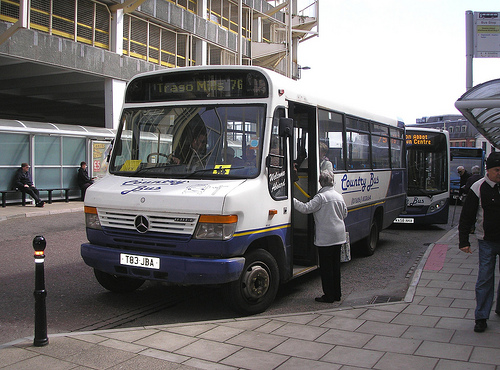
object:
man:
[12, 162, 44, 207]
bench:
[47, 188, 70, 204]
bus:
[79, 64, 407, 315]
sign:
[406, 134, 432, 144]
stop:
[465, 10, 500, 92]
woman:
[292, 173, 347, 303]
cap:
[484, 152, 500, 170]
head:
[486, 151, 500, 183]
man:
[458, 151, 500, 332]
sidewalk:
[0, 230, 499, 369]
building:
[0, 0, 319, 208]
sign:
[464, 10, 499, 58]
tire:
[223, 249, 279, 315]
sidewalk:
[419, 279, 465, 368]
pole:
[33, 235, 51, 347]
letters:
[340, 173, 378, 194]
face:
[78, 100, 261, 316]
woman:
[78, 161, 98, 191]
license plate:
[119, 253, 160, 270]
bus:
[449, 139, 489, 201]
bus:
[391, 126, 450, 224]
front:
[79, 64, 273, 316]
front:
[448, 146, 485, 201]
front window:
[107, 103, 267, 180]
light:
[83, 205, 103, 231]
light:
[193, 214, 239, 240]